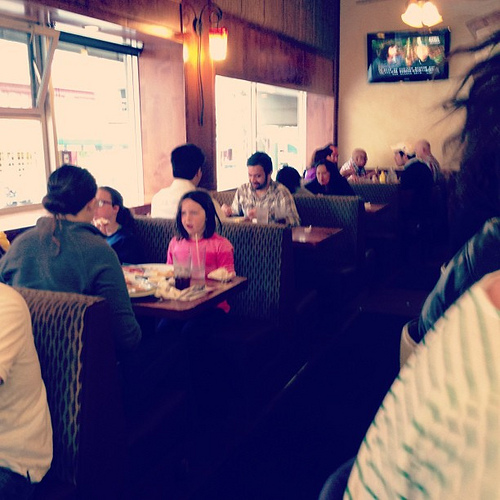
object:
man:
[394, 139, 430, 211]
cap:
[395, 143, 417, 156]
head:
[316, 162, 333, 185]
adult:
[304, 160, 356, 197]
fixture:
[180, 1, 227, 127]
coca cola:
[175, 275, 191, 290]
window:
[0, 15, 59, 117]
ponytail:
[42, 186, 76, 258]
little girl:
[156, 190, 235, 346]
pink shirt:
[167, 233, 235, 277]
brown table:
[120, 264, 246, 318]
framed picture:
[366, 29, 449, 83]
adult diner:
[220, 208, 266, 224]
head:
[170, 144, 204, 187]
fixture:
[401, 0, 442, 28]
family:
[0, 161, 235, 352]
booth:
[6, 215, 291, 334]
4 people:
[303, 143, 377, 197]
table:
[347, 173, 398, 182]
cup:
[257, 205, 268, 224]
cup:
[191, 247, 205, 291]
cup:
[175, 247, 191, 290]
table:
[292, 227, 343, 247]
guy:
[220, 152, 300, 228]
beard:
[250, 177, 268, 191]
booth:
[144, 192, 365, 352]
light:
[208, 29, 228, 60]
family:
[304, 139, 441, 200]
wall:
[337, 0, 498, 173]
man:
[340, 147, 378, 181]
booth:
[295, 183, 457, 236]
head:
[42, 163, 97, 225]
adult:
[0, 163, 140, 353]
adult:
[151, 145, 231, 222]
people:
[415, 140, 441, 182]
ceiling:
[261, 0, 500, 5]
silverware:
[173, 281, 205, 302]